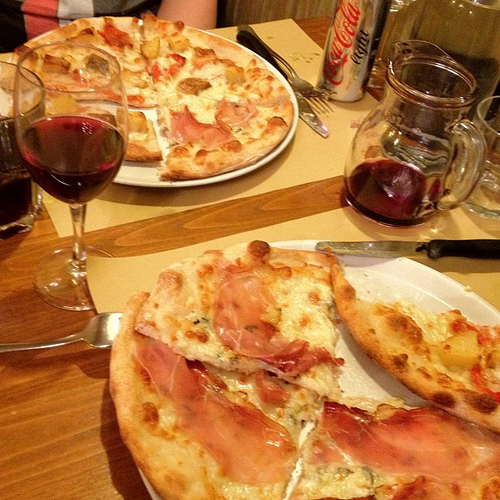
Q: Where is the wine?
A: In a pitcher and in a long stem glass.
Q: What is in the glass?
A: Red wine.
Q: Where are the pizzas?
A: On white plates.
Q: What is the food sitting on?
A: A wooden table.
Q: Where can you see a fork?
A: Underneath pizza slice.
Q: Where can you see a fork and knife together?
A: Near coke can.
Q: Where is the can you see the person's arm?
A: In front of pizza.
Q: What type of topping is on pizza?
A: Ham and cheese.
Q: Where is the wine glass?
A: Left of the fork.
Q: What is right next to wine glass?
A: Soda glass.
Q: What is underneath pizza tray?
A: Placemats.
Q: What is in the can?
A: Soda.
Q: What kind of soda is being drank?
A: Coca Cola Light.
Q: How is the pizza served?
A: On a plate.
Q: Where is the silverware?
A: On the placemats.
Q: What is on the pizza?
A: Ham and Cheese.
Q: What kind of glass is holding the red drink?
A: Wine glass.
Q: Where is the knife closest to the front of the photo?
A: Leaning on the plate.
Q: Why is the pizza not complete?
A: Some was eaten.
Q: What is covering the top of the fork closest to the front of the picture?
A: The edge of the plate.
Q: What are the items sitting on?
A: A table.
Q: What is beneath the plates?
A: Placemats.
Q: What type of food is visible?
A: Pizza.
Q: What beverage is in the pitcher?
A: Wine.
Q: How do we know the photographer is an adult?
A: Glass of wine at her spot.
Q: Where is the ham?
A: On the pizza.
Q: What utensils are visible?
A: Knives and forks.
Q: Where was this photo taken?
A: Restaurant.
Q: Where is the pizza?
A: On white plates.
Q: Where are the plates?
A: On cream colored placemats.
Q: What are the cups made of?
A: Glass.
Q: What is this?
A: Pizza.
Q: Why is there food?
A: For eating.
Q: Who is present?
A: Nobody.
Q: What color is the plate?
A: White.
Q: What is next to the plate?
A: Fork.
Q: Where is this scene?
A: In a pizza parlor.